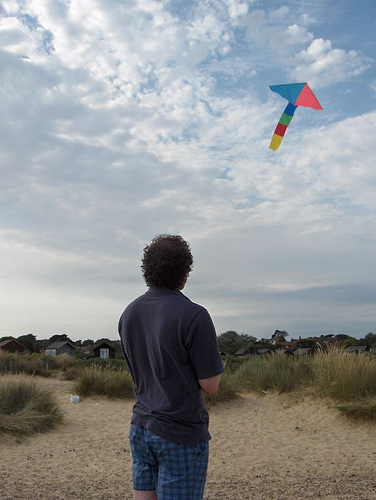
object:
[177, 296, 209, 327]
shoulder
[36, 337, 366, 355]
huts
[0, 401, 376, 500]
sand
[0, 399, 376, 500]
ground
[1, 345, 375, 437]
grass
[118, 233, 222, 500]
man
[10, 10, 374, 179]
clouds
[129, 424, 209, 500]
short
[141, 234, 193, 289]
head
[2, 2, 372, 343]
sky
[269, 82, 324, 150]
kite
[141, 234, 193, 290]
hair